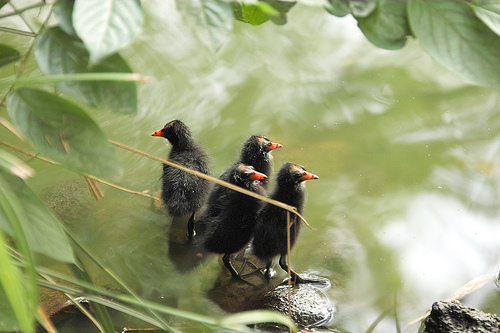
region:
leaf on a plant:
[1, 243, 45, 332]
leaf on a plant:
[3, 166, 88, 274]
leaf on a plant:
[3, 85, 125, 185]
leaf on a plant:
[23, 21, 145, 118]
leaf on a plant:
[68, 1, 150, 63]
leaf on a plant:
[171, 0, 239, 50]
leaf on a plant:
[231, 0, 296, 25]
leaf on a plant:
[323, 4, 374, 17]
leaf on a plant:
[357, 7, 406, 52]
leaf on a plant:
[405, 4, 498, 93]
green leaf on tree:
[6, 83, 119, 183]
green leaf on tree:
[2, 170, 81, 271]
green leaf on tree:
[1, 197, 45, 319]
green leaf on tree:
[0, 244, 32, 331]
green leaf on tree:
[68, 1, 144, 63]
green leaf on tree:
[52, 0, 75, 35]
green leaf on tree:
[178, 2, 233, 52]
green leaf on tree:
[325, 0, 349, 14]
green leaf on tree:
[347, 0, 375, 21]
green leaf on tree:
[354, 0, 415, 50]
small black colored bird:
[256, 163, 326, 290]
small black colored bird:
[199, 164, 271, 286]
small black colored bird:
[201, 130, 272, 214]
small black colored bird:
[149, 120, 204, 243]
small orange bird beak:
[253, 168, 268, 181]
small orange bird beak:
[304, 171, 319, 183]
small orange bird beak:
[268, 138, 283, 149]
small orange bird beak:
[151, 128, 163, 141]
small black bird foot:
[278, 250, 325, 287]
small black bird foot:
[221, 253, 264, 291]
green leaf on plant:
[10, 85, 117, 190]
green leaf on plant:
[1, 166, 81, 272]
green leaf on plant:
[0, 194, 44, 325]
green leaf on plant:
[33, 23, 142, 115]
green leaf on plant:
[71, 1, 143, 75]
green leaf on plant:
[50, 3, 77, 39]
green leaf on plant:
[174, 1, 231, 64]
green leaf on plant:
[351, 3, 381, 20]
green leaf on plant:
[370, 3, 407, 40]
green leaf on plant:
[408, 2, 497, 95]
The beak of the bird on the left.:
[150, 127, 160, 133]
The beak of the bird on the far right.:
[301, 170, 312, 178]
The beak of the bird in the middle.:
[254, 170, 266, 180]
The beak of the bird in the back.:
[266, 138, 281, 148]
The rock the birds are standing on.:
[212, 245, 327, 319]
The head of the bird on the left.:
[159, 116, 194, 154]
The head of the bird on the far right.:
[276, 164, 309, 186]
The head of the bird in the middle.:
[232, 160, 256, 190]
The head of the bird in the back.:
[249, 128, 273, 159]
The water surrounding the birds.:
[68, 21, 486, 328]